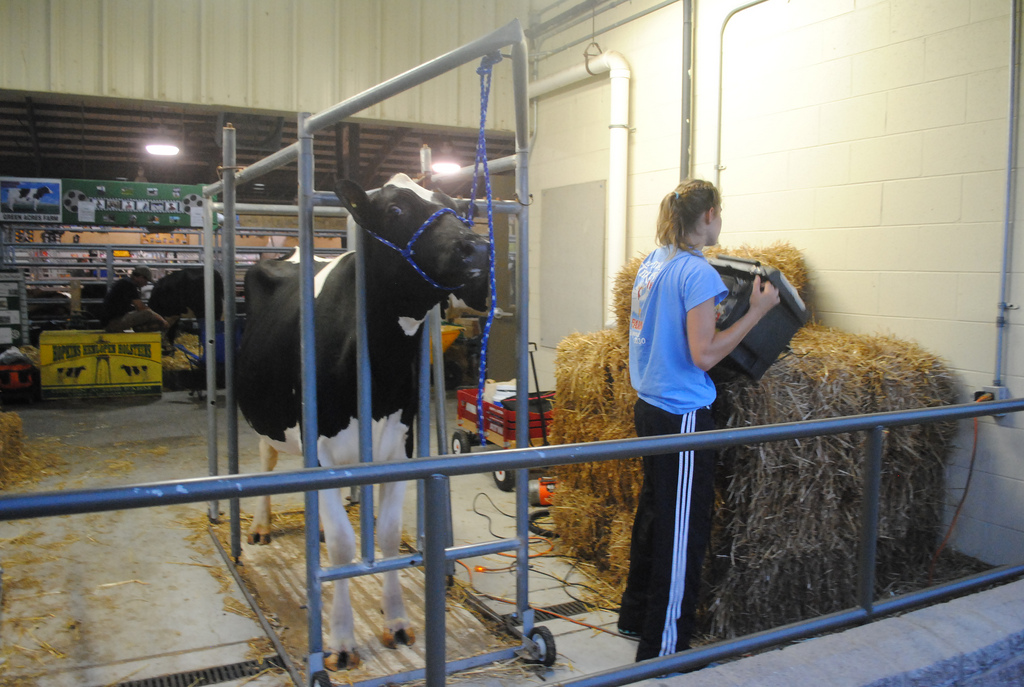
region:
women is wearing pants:
[639, 406, 710, 648]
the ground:
[118, 554, 216, 615]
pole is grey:
[421, 501, 461, 682]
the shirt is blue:
[635, 302, 686, 394]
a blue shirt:
[644, 317, 676, 403]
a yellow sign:
[38, 326, 171, 394]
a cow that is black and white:
[370, 174, 501, 314]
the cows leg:
[322, 497, 361, 573]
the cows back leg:
[246, 434, 281, 473]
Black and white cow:
[219, 169, 504, 670]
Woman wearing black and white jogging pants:
[614, 172, 815, 670]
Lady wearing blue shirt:
[612, 175, 786, 667]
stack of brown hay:
[544, 236, 963, 648]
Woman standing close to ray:
[544, 166, 965, 664]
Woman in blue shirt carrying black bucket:
[608, 175, 818, 663]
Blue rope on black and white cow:
[220, 34, 533, 674]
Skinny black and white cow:
[222, 156, 501, 675]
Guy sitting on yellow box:
[30, 258, 180, 413]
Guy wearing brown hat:
[90, 260, 177, 358]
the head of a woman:
[647, 169, 756, 258]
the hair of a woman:
[664, 186, 738, 292]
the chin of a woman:
[680, 219, 750, 267]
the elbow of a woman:
[651, 293, 741, 392]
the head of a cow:
[318, 140, 508, 346]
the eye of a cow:
[362, 191, 445, 236]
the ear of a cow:
[313, 134, 431, 230]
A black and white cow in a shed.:
[243, 171, 525, 668]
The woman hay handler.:
[619, 174, 815, 658]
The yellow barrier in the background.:
[40, 327, 165, 395]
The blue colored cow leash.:
[346, 55, 536, 451]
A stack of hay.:
[553, 242, 945, 626]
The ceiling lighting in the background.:
[138, 133, 464, 176]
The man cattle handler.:
[103, 261, 224, 334]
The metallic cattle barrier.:
[0, 395, 1023, 683]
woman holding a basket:
[592, 169, 834, 682]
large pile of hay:
[561, 239, 957, 620]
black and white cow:
[201, 141, 473, 680]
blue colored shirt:
[599, 248, 721, 414]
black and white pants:
[618, 387, 737, 647]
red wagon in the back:
[444, 340, 565, 474]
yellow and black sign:
[34, 324, 170, 402]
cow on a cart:
[181, 105, 577, 676]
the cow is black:
[211, 171, 516, 457]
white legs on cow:
[244, 379, 432, 668]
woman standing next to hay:
[598, 164, 925, 668]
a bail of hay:
[511, 299, 964, 616]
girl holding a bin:
[614, 240, 814, 433]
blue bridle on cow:
[347, 76, 562, 378]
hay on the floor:
[4, 427, 109, 680]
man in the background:
[83, 244, 173, 343]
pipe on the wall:
[528, 47, 662, 279]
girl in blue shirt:
[509, 98, 931, 471]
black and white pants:
[549, 394, 765, 606]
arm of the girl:
[676, 266, 787, 406]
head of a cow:
[252, 121, 567, 360]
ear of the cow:
[302, 145, 400, 267]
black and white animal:
[95, 161, 554, 564]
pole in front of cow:
[329, 389, 614, 563]